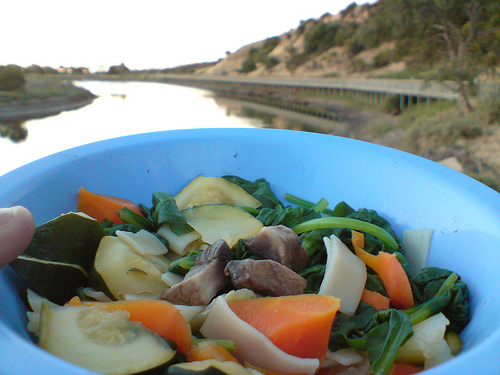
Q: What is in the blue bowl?
A: Food.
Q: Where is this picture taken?
A: In nature.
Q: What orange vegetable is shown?
A: Carrot.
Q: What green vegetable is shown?
A: Spinach.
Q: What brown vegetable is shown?
A: Mushrooms.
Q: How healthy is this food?
A: Very much.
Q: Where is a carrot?
A: Blue bowl.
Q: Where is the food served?
A: Bowl.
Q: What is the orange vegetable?
A: Carrot.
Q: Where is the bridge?
A: Alongside the waterway.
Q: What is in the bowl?
A: Salad with noodles.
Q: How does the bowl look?
A: Deep and blue.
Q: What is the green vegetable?
A: Spinach.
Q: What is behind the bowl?
A: Waterway.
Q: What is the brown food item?
A: Mushrooms.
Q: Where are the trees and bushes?
A: Growing on hillside.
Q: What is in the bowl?
A: Meat and vegetables.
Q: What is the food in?
A: A blue bowl.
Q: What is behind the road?
A: Hills.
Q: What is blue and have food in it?
A: A bowl.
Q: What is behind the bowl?
A: A river.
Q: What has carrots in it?
A: A blue bowl.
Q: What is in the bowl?
A: A salad.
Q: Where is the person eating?
A: By a river.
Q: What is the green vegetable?
A: Spinach.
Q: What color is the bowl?
A: Blue.